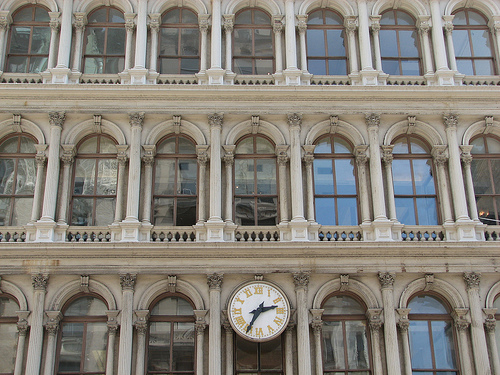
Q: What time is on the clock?
A: 2:35.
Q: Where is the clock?
A: On the building.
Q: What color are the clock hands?
A: Black.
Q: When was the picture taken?
A: Daytime.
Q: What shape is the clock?
A: Round.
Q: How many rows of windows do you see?
A: Three.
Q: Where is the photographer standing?
A: In front of the building.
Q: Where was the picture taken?
A: On a city street.